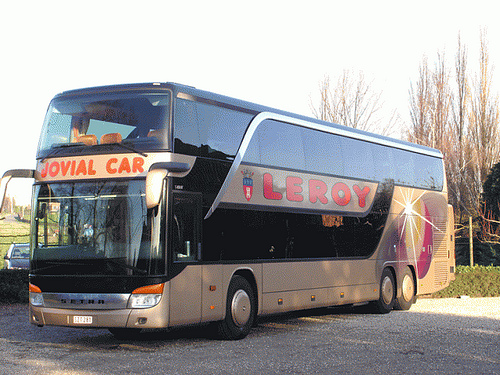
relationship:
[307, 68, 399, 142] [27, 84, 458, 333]
tree behind bus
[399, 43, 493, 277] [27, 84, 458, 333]
tree behind bus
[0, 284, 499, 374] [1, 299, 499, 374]
ground has shadow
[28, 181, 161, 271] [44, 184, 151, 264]
window has reflection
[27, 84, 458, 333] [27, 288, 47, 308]
bus has headlight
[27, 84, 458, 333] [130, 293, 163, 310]
bus has headlight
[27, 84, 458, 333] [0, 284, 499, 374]
bus parked on ground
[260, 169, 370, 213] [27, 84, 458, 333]
word leroy on side of bus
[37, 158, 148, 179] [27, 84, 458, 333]
jovial car on front of bus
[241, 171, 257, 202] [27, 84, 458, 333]
design on side of bus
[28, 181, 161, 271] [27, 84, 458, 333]
window on front of bus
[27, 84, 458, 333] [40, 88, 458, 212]
bus has top cabin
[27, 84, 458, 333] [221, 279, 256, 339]
bus has tire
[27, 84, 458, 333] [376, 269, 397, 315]
bus has tire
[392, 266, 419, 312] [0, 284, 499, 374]
tire on top of ground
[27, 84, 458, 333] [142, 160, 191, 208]
bus has side mirror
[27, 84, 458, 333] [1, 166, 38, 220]
bus has side mirror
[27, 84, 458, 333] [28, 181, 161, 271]
bus has window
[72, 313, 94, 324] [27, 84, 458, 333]
license plate on front of bus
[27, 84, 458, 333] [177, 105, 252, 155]
bus has side window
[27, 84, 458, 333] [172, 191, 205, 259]
bus has side window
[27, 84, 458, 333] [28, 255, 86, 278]
bus has windshield washer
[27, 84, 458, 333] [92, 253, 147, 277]
bus has windshield wiper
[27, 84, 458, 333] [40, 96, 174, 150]
bus has top window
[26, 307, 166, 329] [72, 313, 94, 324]
bumper has license plate